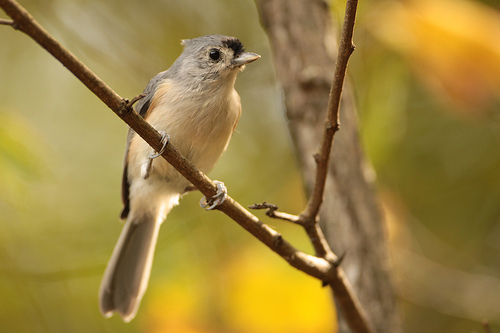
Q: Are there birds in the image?
A: Yes, there is a bird.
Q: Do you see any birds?
A: Yes, there is a bird.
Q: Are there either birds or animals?
A: Yes, there is a bird.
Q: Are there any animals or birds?
A: Yes, there is a bird.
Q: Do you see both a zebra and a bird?
A: No, there is a bird but no zebras.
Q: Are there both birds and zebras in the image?
A: No, there is a bird but no zebras.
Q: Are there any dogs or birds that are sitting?
A: Yes, the bird is sitting.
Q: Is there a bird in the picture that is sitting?
A: Yes, there is a bird that is sitting.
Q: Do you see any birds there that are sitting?
A: Yes, there is a bird that is sitting.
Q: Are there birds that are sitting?
A: Yes, there is a bird that is sitting.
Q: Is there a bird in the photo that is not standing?
A: Yes, there is a bird that is sitting.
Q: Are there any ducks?
A: No, there are no ducks.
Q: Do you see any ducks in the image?
A: No, there are no ducks.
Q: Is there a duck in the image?
A: No, there are no ducks.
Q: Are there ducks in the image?
A: No, there are no ducks.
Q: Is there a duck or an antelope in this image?
A: No, there are no ducks or antelopes.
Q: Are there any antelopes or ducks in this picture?
A: No, there are no ducks or antelopes.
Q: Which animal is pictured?
A: The animal is a bird.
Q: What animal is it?
A: The animal is a bird.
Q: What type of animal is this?
A: This is a bird.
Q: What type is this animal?
A: This is a bird.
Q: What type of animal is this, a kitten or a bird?
A: This is a bird.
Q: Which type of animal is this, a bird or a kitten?
A: This is a bird.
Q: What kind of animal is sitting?
A: The animal is a bird.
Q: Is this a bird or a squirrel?
A: This is a bird.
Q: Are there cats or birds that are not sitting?
A: No, there is a bird but it is sitting.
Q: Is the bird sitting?
A: Yes, the bird is sitting.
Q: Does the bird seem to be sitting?
A: Yes, the bird is sitting.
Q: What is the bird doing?
A: The bird is sitting.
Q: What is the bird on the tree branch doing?
A: The bird is sitting.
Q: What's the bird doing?
A: The bird is sitting.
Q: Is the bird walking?
A: No, the bird is sitting.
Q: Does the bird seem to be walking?
A: No, the bird is sitting.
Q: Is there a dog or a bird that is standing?
A: No, there is a bird but it is sitting.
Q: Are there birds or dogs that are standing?
A: No, there is a bird but it is sitting.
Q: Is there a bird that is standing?
A: No, there is a bird but it is sitting.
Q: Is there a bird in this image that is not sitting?
A: No, there is a bird but it is sitting.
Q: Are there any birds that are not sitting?
A: No, there is a bird but it is sitting.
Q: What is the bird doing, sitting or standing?
A: The bird is sitting.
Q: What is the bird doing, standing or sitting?
A: The bird is sitting.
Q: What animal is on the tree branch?
A: The bird is on the tree branch.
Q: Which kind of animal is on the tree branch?
A: The animal is a bird.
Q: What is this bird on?
A: The bird is on the tree branch.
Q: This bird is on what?
A: The bird is on the tree branch.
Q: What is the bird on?
A: The bird is on the tree branch.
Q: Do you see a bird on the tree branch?
A: Yes, there is a bird on the tree branch.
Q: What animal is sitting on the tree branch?
A: The bird is sitting on the tree branch.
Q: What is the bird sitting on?
A: The bird is sitting on the tree branch.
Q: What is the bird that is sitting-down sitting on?
A: The bird is sitting on the tree branch.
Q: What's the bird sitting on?
A: The bird is sitting on the tree branch.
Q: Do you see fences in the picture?
A: No, there are no fences.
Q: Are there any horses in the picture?
A: No, there are no horses.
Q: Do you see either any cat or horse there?
A: No, there are no horses or cats.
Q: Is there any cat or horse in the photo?
A: No, there are no horses or cats.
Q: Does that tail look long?
A: Yes, the tail is long.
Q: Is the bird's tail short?
A: No, the tail is long.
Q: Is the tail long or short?
A: The tail is long.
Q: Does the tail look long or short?
A: The tail is long.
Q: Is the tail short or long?
A: The tail is long.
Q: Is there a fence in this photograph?
A: No, there are no fences.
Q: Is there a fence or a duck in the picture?
A: No, there are no fences or ducks.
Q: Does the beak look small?
A: Yes, the beak is small.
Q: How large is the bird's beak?
A: The beak is small.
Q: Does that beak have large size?
A: No, the beak is small.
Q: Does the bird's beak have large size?
A: No, the beak is small.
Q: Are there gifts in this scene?
A: No, there are no gifts.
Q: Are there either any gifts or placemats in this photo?
A: No, there are no gifts or placemats.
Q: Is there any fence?
A: No, there are no fences.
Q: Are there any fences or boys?
A: No, there are no fences or boys.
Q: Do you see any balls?
A: No, there are no balls.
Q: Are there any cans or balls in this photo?
A: No, there are no balls or cans.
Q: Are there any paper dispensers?
A: No, there are no paper dispensers.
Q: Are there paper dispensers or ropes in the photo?
A: No, there are no paper dispensers or ropes.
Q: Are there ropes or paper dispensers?
A: No, there are no paper dispensers or ropes.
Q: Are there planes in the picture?
A: No, there are no planes.